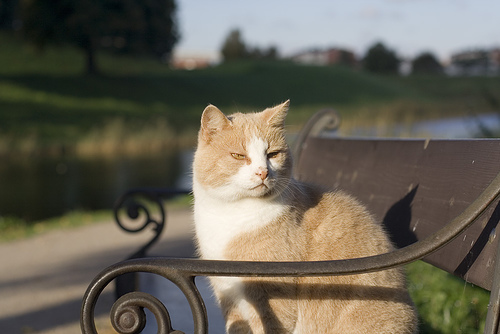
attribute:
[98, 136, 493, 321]
metal bench — black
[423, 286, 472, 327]
grass — green, patch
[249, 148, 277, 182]
nose — white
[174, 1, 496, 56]
sky — clear, blue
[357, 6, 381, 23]
cloud — light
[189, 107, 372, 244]
cat — sitting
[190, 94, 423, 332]
cat — golden, sitting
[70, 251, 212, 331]
design — metal, curved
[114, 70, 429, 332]
cat — orange, white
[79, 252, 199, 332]
arm — iron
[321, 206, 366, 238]
fur — golden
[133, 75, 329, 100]
grass — green